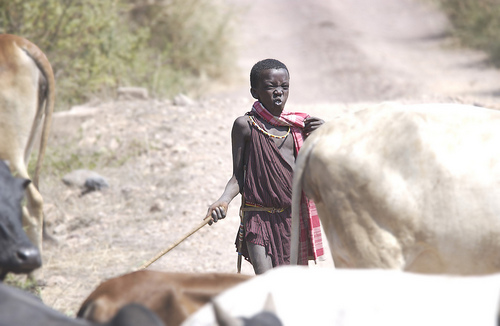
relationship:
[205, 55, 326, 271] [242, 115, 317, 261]
child wearing clothes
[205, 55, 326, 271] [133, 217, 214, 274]
child carrying stick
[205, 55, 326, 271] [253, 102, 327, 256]
child wearing scarf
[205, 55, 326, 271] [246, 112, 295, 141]
child wearing necklace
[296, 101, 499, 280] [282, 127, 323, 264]
cow has tail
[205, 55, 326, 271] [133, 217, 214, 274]
child holding stick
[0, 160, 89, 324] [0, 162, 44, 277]
cow has face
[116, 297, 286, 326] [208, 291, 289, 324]
cow has horns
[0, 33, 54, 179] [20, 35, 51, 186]
cow has tail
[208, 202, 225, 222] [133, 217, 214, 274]
fingers around stick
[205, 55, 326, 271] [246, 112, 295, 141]
child has necklace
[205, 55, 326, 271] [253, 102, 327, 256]
boy has scarf